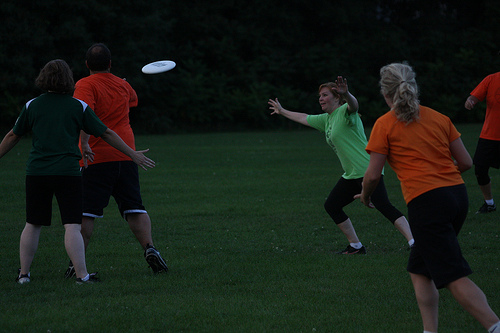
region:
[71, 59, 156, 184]
lady wearing short sleeve orange T shirt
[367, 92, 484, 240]
lady wearing orange short sleeve T shirt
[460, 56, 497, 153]
person wearing orange short sleeve T shirt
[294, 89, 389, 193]
lady wearing green short sleeve T shirt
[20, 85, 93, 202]
lady wearing balck short sleeve T shirt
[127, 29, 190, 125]
whit Frisbee in the air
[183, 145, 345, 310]
grfeen grass in a park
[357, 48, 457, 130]
lady with blonde hair in a ponytail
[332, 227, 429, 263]
white ankle socks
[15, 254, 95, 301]
black and white tennis shoes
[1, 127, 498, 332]
The grass is green.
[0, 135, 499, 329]
The grass is short.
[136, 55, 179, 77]
The frisbee is white.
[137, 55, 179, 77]
The frisbee is made of plastic.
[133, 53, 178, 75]
The frisbee is flying.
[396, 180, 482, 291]
The person is wearing shorts.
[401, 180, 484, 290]
The shorts are black.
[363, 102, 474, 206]
The person is wearing an orange top.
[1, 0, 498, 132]
Trees are in the background.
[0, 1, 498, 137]
The trees are green.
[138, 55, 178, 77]
The frisbee is in mid air.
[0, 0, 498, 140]
The trees have leaves.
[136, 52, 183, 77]
it is a white frisbee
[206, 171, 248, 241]
it is the grass below the people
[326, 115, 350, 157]
this woman is wearing a green shirt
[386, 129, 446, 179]
this woman is wearing a orange shirt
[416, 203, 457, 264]
this woman is wearing black shorts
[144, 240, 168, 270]
this man is wearing black tennis shoes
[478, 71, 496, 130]
this ma is wearing an orange t shirt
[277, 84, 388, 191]
this woman is playing frisbee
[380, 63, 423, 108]
this woman has blonde hair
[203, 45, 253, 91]
bushes in the background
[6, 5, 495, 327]
a group of adults playing with a frisbee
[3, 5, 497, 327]
a sports team playing frisbee on a field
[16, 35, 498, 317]
five adults running toward a frisbee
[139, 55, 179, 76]
white frisbee flying through the air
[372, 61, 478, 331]
blonde woman wearing an orange shirt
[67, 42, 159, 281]
man in orange shirt throwing a frisbee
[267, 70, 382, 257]
woman in a green shirt running toward a frisbee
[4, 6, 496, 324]
a group of people playing a sport at night time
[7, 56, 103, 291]
a brown-haired woman standing with her arms outstretched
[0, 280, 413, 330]
short green grass in an open field